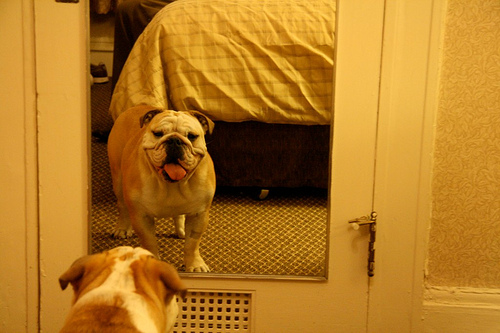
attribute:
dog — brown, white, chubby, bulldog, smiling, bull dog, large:
[52, 245, 187, 332]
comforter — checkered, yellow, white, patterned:
[108, 0, 337, 121]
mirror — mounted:
[77, 4, 336, 281]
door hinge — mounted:
[349, 210, 378, 274]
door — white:
[18, 0, 398, 333]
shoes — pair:
[85, 58, 113, 84]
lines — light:
[182, 37, 299, 70]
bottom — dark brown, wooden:
[208, 121, 328, 190]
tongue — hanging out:
[163, 164, 190, 180]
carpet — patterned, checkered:
[222, 199, 317, 271]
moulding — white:
[412, 281, 496, 313]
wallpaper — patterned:
[457, 79, 499, 207]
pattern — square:
[177, 22, 241, 64]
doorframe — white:
[2, 3, 38, 332]